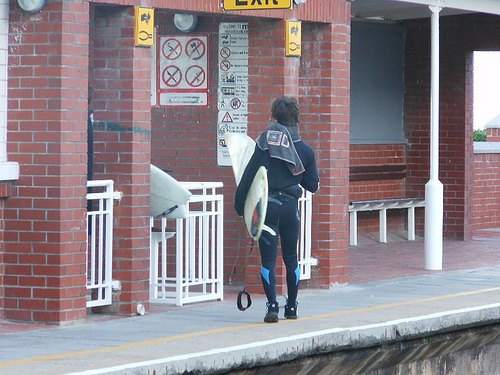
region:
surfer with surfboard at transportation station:
[5, 5, 498, 373]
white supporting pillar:
[424, 2, 447, 272]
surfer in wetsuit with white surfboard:
[222, 94, 307, 327]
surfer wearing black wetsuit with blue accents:
[235, 91, 307, 320]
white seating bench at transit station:
[349, 195, 422, 239]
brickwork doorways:
[2, 1, 357, 315]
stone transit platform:
[3, 261, 496, 374]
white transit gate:
[149, 178, 226, 309]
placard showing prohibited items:
[156, 34, 208, 107]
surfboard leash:
[238, 233, 251, 311]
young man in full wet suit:
[257, 87, 319, 318]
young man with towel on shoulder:
[263, 92, 320, 316]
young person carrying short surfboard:
[224, 97, 311, 324]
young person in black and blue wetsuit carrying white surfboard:
[226, 95, 311, 317]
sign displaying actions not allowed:
[154, 27, 211, 112]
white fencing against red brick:
[175, 167, 235, 270]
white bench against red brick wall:
[351, 149, 419, 253]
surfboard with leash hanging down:
[221, 127, 269, 317]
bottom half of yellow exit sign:
[221, 1, 303, 15]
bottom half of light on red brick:
[167, 9, 204, 34]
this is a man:
[232, 85, 344, 326]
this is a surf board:
[202, 100, 287, 248]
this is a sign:
[178, 65, 215, 90]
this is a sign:
[160, 63, 184, 88]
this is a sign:
[184, 36, 212, 60]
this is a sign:
[162, 34, 181, 60]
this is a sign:
[219, 106, 236, 126]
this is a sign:
[228, 92, 244, 114]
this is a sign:
[214, 58, 236, 71]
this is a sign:
[212, 39, 232, 61]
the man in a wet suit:
[230, 97, 317, 324]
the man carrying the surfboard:
[223, 95, 318, 325]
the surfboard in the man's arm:
[221, 130, 276, 240]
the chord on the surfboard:
[228, 217, 253, 311]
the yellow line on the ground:
[1, 284, 498, 365]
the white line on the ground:
[60, 302, 497, 374]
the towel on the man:
[255, 122, 305, 177]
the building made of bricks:
[0, 0, 498, 326]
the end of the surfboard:
[149, 160, 190, 222]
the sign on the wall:
[215, 22, 247, 166]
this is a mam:
[252, 88, 315, 301]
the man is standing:
[239, 91, 312, 312]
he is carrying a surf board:
[233, 178, 267, 248]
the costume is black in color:
[274, 173, 301, 226]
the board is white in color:
[252, 177, 268, 199]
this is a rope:
[237, 263, 245, 278]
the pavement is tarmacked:
[387, 285, 426, 317]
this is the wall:
[323, 36, 353, 78]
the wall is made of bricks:
[302, 30, 351, 80]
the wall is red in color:
[20, 66, 72, 133]